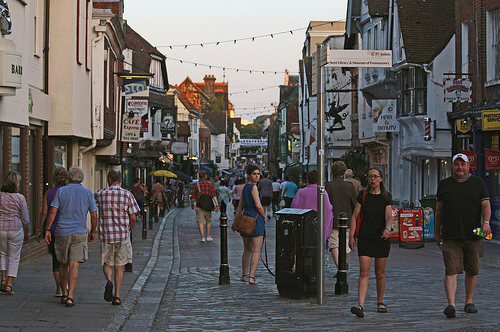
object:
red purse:
[352, 187, 368, 237]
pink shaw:
[292, 184, 334, 242]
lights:
[182, 45, 188, 51]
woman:
[351, 167, 394, 319]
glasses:
[363, 174, 382, 181]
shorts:
[437, 239, 479, 274]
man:
[433, 152, 493, 318]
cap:
[452, 152, 470, 161]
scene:
[1, 0, 500, 331]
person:
[45, 167, 99, 307]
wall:
[46, 0, 75, 136]